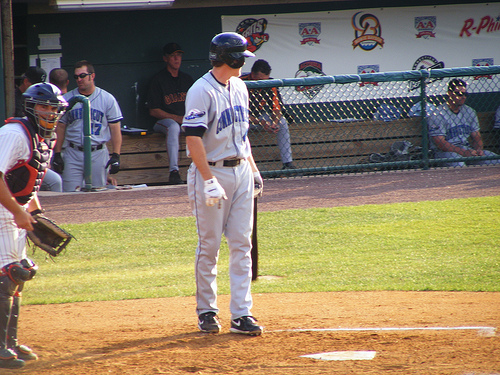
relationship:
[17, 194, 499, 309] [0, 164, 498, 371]
field on field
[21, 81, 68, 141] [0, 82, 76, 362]
batting helmet on behind hitter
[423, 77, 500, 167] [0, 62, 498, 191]
baseball player in dugout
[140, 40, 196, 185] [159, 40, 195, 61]
player wearing black hat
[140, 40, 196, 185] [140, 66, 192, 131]
player wearing shirt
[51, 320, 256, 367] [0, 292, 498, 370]
batter's shadow on dirt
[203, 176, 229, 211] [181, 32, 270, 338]
baseball glove on baseball player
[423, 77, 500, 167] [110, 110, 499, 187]
baseball player sitting on bench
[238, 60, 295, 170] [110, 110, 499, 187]
player sitting on bench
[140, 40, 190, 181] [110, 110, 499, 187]
player sitting on bench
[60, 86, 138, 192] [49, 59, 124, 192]
gray uniform on man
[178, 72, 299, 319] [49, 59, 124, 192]
baseball uniform on man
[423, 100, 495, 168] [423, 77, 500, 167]
uniform on baseball player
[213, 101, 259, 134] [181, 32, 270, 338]
blue writing on baseball player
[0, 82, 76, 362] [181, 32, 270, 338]
behind hitter behind baseball player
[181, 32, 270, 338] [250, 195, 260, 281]
baseball player holding bat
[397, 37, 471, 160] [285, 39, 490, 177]
man in dugout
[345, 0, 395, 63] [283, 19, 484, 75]
logo on banner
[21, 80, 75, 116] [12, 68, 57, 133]
blue helmet on head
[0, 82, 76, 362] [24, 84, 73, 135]
behind hitter has safety equipment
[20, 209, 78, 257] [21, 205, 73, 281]
catchers mitt on hand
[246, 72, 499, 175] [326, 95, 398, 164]
fence link fence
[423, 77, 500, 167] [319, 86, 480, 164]
baseball player sitting on bench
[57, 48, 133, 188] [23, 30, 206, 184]
man standing in dugout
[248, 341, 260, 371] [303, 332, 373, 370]
dirt around plate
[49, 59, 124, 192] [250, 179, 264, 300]
man at bat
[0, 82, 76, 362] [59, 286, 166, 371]
behind hitter on dirt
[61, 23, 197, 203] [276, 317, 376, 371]
dugout behind plate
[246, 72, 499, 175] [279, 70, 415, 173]
fence in front of dugout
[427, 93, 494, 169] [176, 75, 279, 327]
gray uniform wearing uniform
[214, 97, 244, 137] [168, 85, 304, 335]
writing on uniform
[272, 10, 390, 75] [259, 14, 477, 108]
banner on wall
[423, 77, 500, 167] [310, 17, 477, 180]
baseball player in dugout